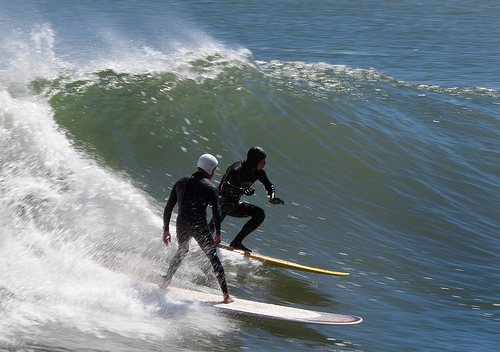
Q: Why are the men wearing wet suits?
A: To stay warm.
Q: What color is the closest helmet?
A: White.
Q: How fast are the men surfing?
A: Very fast.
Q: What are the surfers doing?
A: Surfing.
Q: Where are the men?
A: In the ocean.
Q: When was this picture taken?
A: In the day time.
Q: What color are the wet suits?
A: Black.